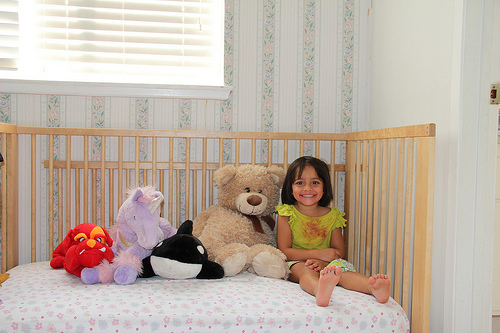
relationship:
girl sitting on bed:
[277, 157, 390, 308] [0, 122, 434, 332]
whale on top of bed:
[136, 220, 223, 279] [0, 122, 434, 332]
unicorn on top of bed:
[81, 185, 178, 284] [0, 122, 434, 332]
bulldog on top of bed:
[50, 223, 114, 277] [0, 122, 434, 332]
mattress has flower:
[2, 261, 410, 333] [164, 318, 168, 322]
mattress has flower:
[2, 261, 410, 333] [57, 314, 62, 318]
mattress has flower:
[2, 261, 410, 333] [258, 318, 265, 323]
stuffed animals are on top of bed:
[51, 165, 293, 284] [0, 122, 434, 332]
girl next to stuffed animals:
[277, 157, 390, 308] [51, 165, 293, 284]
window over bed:
[1, 1, 233, 100] [0, 122, 434, 332]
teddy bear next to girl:
[191, 164, 286, 279] [277, 157, 390, 308]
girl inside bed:
[277, 157, 390, 308] [0, 122, 434, 332]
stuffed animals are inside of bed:
[51, 165, 293, 284] [0, 122, 434, 332]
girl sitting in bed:
[277, 157, 390, 308] [0, 122, 434, 332]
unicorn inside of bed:
[81, 185, 178, 284] [0, 122, 434, 332]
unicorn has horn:
[81, 185, 178, 284] [150, 195, 164, 212]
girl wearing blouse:
[277, 157, 390, 308] [276, 204, 347, 250]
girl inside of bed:
[277, 157, 390, 308] [0, 122, 434, 332]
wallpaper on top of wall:
[0, 1, 375, 264] [1, 0, 362, 264]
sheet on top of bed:
[1, 261, 408, 333] [0, 122, 434, 332]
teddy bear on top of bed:
[191, 164, 286, 279] [0, 122, 434, 332]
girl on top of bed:
[277, 157, 390, 308] [0, 122, 434, 332]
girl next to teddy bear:
[277, 157, 390, 308] [191, 164, 286, 279]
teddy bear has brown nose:
[191, 164, 286, 279] [248, 195, 263, 205]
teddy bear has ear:
[191, 164, 286, 279] [215, 164, 236, 184]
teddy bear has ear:
[191, 164, 286, 279] [269, 166, 285, 186]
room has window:
[0, 0, 499, 331] [1, 1, 233, 100]